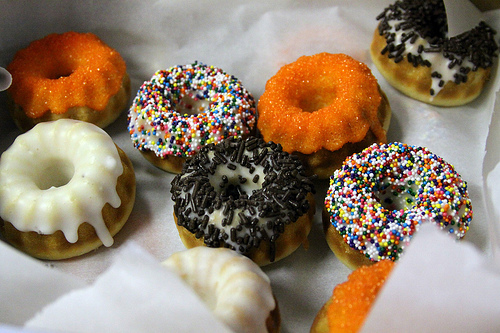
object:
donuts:
[320, 140, 472, 271]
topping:
[0, 117, 122, 230]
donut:
[125, 60, 256, 174]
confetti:
[146, 83, 174, 138]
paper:
[174, 11, 301, 58]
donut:
[169, 136, 319, 267]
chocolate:
[221, 193, 261, 227]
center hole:
[171, 95, 211, 116]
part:
[195, 163, 206, 177]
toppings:
[254, 52, 381, 155]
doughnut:
[5, 31, 131, 133]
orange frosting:
[78, 82, 93, 95]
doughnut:
[159, 245, 279, 332]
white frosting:
[237, 270, 253, 311]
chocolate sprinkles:
[418, 17, 439, 38]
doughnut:
[368, 0, 499, 108]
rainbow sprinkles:
[351, 179, 371, 213]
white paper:
[441, 0, 500, 45]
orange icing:
[35, 43, 59, 57]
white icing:
[87, 209, 114, 248]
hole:
[34, 157, 79, 190]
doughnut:
[0, 119, 137, 262]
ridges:
[351, 121, 380, 143]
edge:
[267, 218, 285, 234]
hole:
[220, 180, 256, 202]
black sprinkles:
[186, 181, 208, 213]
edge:
[420, 215, 485, 254]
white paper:
[360, 221, 500, 333]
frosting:
[274, 87, 291, 113]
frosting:
[106, 186, 126, 209]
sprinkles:
[160, 71, 220, 90]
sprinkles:
[253, 142, 275, 162]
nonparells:
[123, 5, 143, 49]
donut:
[256, 52, 391, 179]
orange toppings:
[336, 57, 357, 74]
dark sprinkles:
[245, 218, 269, 248]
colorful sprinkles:
[196, 66, 219, 87]